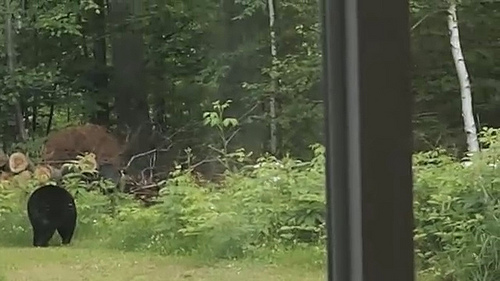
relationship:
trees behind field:
[24, 7, 329, 180] [81, 229, 140, 257]